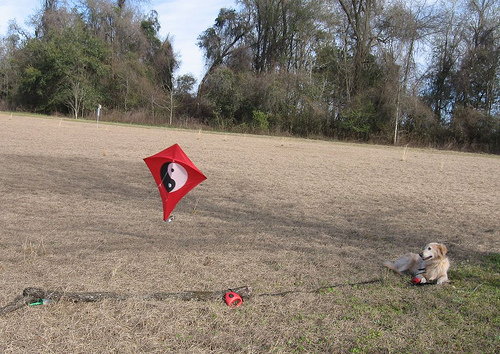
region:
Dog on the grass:
[387, 237, 462, 288]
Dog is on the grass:
[384, 237, 455, 289]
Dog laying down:
[377, 235, 457, 288]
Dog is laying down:
[382, 232, 454, 291]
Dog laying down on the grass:
[382, 235, 454, 290]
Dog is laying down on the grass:
[379, 235, 456, 288]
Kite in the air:
[142, 135, 214, 225]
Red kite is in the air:
[139, 139, 211, 228]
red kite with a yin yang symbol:
[138, 141, 209, 221]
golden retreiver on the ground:
[385, 231, 450, 288]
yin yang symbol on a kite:
[160, 163, 190, 190]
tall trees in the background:
[2, 10, 496, 161]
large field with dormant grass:
[1, 108, 495, 349]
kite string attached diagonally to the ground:
[30, 171, 168, 302]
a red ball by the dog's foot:
[410, 277, 426, 289]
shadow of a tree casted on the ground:
[8, 146, 494, 287]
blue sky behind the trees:
[0, 3, 493, 116]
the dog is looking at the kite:
[387, 237, 447, 286]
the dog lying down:
[385, 240, 449, 283]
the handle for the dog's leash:
[221, 289, 243, 308]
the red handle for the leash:
[222, 288, 242, 307]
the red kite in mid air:
[141, 142, 206, 222]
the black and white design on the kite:
[159, 162, 188, 192]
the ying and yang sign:
[158, 160, 186, 192]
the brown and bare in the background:
[0, 0, 496, 152]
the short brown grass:
[0, 110, 499, 353]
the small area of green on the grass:
[170, 255, 498, 350]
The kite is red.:
[140, 143, 202, 223]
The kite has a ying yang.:
[142, 143, 207, 225]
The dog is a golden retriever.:
[378, 236, 462, 288]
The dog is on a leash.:
[211, 239, 449, 304]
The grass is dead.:
[218, 142, 425, 224]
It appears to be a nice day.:
[1, 1, 498, 118]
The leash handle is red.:
[218, 289, 248, 307]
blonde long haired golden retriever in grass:
[373, 231, 461, 313]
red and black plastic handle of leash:
[210, 271, 255, 316]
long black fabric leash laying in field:
[249, 272, 399, 315]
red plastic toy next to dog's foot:
[405, 264, 437, 298]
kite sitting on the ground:
[130, 135, 212, 244]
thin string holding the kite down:
[48, 189, 155, 313]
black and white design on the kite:
[156, 156, 192, 198]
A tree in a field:
[384, 4, 415, 160]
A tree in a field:
[332, 2, 385, 149]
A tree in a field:
[318, 18, 354, 145]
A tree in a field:
[263, 15, 330, 125]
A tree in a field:
[286, 15, 306, 128]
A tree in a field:
[246, 5, 263, 117]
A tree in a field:
[185, 17, 254, 141]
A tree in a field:
[158, 40, 186, 111]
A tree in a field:
[11, 23, 96, 118]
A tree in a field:
[166, 87, 193, 127]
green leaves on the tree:
[245, 66, 292, 113]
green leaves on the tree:
[331, 70, 367, 125]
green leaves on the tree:
[290, 81, 322, 128]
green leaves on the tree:
[43, 36, 86, 84]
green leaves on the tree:
[95, 52, 142, 97]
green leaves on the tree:
[202, 63, 243, 99]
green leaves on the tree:
[283, 49, 340, 113]